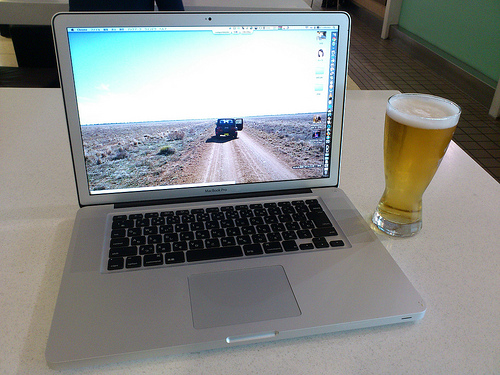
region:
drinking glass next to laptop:
[375, 90, 454, 242]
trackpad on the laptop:
[188, 265, 302, 326]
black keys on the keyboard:
[105, 189, 344, 272]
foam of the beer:
[382, 93, 455, 127]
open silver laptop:
[36, 9, 431, 359]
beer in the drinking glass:
[384, 90, 449, 224]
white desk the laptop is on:
[5, 89, 493, 374]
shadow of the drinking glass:
[295, 213, 389, 263]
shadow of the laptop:
[23, 211, 75, 371]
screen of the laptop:
[66, 23, 333, 190]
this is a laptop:
[103, 130, 268, 264]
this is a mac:
[199, 197, 287, 316]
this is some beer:
[361, 132, 451, 360]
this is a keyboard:
[205, 205, 225, 245]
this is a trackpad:
[207, 285, 275, 335]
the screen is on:
[101, 68, 239, 228]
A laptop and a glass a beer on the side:
[17, 0, 464, 367]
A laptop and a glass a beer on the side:
[31, 5, 465, 372]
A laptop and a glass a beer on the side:
[28, 5, 465, 360]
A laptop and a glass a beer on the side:
[34, 6, 471, 360]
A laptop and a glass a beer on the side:
[30, 2, 465, 366]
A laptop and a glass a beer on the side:
[37, 5, 464, 365]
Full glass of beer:
[365, 87, 464, 242]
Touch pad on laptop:
[186, 260, 303, 332]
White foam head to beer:
[386, 87, 461, 130]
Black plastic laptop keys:
[106, 194, 351, 273]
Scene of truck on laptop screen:
[63, 23, 340, 196]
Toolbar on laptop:
[66, 26, 336, 33]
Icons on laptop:
[312, 30, 329, 174]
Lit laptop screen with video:
[36, 17, 442, 374]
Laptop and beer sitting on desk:
[5, 12, 494, 374]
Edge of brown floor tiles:
[350, 25, 439, 90]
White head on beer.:
[390, 102, 449, 137]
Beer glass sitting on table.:
[358, 90, 428, 257]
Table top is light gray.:
[422, 244, 477, 326]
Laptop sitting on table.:
[62, 149, 354, 306]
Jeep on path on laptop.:
[208, 109, 243, 147]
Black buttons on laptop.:
[145, 211, 290, 248]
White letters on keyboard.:
[164, 220, 265, 250]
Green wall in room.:
[433, 17, 497, 49]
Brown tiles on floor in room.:
[408, 58, 440, 95]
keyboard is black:
[141, 211, 286, 251]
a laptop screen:
[56, 17, 341, 190]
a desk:
[441, 275, 486, 325]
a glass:
[382, 85, 452, 225]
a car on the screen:
[213, 117, 249, 141]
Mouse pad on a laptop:
[177, 260, 303, 330]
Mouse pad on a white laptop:
[181, 263, 305, 335]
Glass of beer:
[371, 80, 466, 237]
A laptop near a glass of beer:
[26, 1, 473, 372]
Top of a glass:
[378, 88, 465, 149]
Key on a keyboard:
[328, 235, 345, 248]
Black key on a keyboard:
[327, 236, 346, 251]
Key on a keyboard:
[106, 255, 122, 269]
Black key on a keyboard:
[104, 252, 124, 272]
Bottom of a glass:
[366, 189, 430, 241]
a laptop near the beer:
[50, 12, 429, 345]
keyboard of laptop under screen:
[101, 203, 360, 275]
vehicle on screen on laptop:
[210, 112, 246, 144]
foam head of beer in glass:
[385, 89, 453, 131]